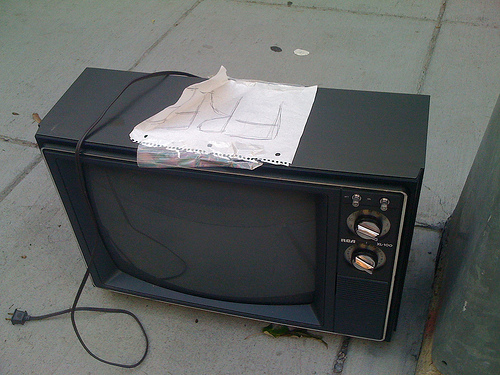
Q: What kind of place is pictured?
A: It is a sidewalk.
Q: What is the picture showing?
A: It is showing a sidewalk.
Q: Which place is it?
A: It is a sidewalk.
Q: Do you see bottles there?
A: No, there are no bottles.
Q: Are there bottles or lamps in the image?
A: No, there are no bottles or lamps.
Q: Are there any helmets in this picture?
A: No, there are no helmets.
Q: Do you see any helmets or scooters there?
A: No, there are no helmets or scooters.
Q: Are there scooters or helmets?
A: No, there are no helmets or scooters.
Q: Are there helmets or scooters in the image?
A: No, there are no helmets or scooters.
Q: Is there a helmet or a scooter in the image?
A: No, there are no helmets or scooters.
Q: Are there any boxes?
A: No, there are no boxes.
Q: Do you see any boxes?
A: No, there are no boxes.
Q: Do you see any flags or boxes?
A: No, there are no boxes or flags.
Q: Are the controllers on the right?
A: Yes, the controllers are on the right of the image.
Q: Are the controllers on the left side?
A: No, the controllers are on the right of the image.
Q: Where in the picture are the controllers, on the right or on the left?
A: The controllers are on the right of the image.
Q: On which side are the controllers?
A: The controllers are on the right of the image.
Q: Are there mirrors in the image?
A: No, there are no mirrors.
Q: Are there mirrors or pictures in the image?
A: No, there are no mirrors or pictures.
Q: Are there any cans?
A: No, there are no cans.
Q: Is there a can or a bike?
A: No, there are no cans or bikes.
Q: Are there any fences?
A: No, there are no fences.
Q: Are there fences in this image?
A: No, there are no fences.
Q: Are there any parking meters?
A: No, there are no parking meters.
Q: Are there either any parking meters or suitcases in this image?
A: No, there are no parking meters or suitcases.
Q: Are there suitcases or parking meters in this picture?
A: No, there are no parking meters or suitcases.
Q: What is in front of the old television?
A: The leaf is in front of the television.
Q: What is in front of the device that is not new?
A: The leaf is in front of the television.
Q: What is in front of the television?
A: The leaf is in front of the television.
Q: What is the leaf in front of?
A: The leaf is in front of the TV.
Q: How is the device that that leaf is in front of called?
A: The device is a television.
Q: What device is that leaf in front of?
A: The leaf is in front of the TV.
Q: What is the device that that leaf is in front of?
A: The device is a television.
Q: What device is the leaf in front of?
A: The leaf is in front of the TV.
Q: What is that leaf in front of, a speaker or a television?
A: The leaf is in front of a television.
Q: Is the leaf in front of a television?
A: Yes, the leaf is in front of a television.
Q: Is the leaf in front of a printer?
A: No, the leaf is in front of a television.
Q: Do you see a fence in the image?
A: No, there are no fences.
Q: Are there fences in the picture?
A: No, there are no fences.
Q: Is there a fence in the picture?
A: No, there are no fences.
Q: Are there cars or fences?
A: No, there are no fences or cars.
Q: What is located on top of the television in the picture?
A: The sign is on top of the television.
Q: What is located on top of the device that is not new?
A: The sign is on top of the television.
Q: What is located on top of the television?
A: The sign is on top of the television.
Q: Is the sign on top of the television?
A: Yes, the sign is on top of the television.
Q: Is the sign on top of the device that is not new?
A: Yes, the sign is on top of the television.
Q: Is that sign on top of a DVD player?
A: No, the sign is on top of the television.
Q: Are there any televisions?
A: Yes, there is a television.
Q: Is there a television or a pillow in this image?
A: Yes, there is a television.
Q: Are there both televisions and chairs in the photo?
A: No, there is a television but no chairs.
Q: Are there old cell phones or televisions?
A: Yes, there is an old television.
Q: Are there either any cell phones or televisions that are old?
A: Yes, the television is old.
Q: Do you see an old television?
A: Yes, there is an old television.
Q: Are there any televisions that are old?
A: Yes, there is a television that is old.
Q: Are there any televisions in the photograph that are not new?
A: Yes, there is a old television.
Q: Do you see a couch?
A: No, there are no couches.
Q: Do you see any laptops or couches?
A: No, there are no couches or laptops.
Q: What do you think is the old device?
A: The device is a television.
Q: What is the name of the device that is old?
A: The device is a television.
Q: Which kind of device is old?
A: The device is a television.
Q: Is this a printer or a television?
A: This is a television.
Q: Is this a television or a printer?
A: This is a television.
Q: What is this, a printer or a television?
A: This is a television.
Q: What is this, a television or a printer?
A: This is a television.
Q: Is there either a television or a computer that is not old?
A: No, there is a television but it is old.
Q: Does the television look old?
A: Yes, the television is old.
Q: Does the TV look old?
A: Yes, the TV is old.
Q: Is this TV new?
A: No, the TV is old.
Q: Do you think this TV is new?
A: No, the TV is old.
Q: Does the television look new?
A: No, the television is old.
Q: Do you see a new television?
A: No, there is a television but it is old.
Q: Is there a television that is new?
A: No, there is a television but it is old.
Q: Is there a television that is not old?
A: No, there is a television but it is old.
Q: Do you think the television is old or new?
A: The television is old.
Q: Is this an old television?
A: Yes, this is an old television.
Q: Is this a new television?
A: No, this is an old television.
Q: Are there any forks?
A: No, there are no forks.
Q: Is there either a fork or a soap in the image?
A: No, there are no forks or soaps.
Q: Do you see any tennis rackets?
A: No, there are no tennis rackets.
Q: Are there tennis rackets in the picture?
A: No, there are no tennis rackets.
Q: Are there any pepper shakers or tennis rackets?
A: No, there are no tennis rackets or pepper shakers.